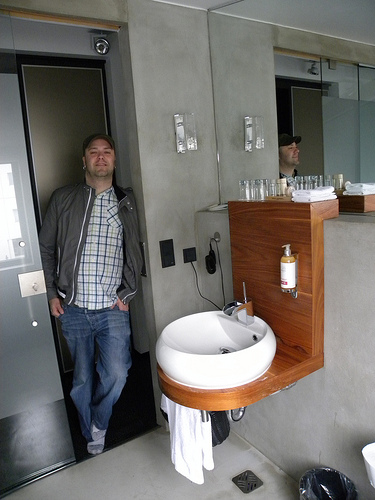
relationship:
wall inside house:
[133, 12, 211, 116] [236, 28, 294, 68]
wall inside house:
[0, 0, 375, 499] [236, 28, 294, 68]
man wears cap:
[42, 122, 138, 426] [81, 129, 121, 147]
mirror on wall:
[208, 4, 372, 217] [133, 12, 211, 116]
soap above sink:
[279, 243, 297, 293] [156, 308, 286, 389]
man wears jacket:
[42, 122, 138, 426] [53, 182, 144, 308]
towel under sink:
[158, 394, 215, 486] [156, 308, 286, 389]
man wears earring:
[42, 122, 138, 426] [78, 165, 93, 177]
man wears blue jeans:
[42, 122, 138, 426] [56, 303, 132, 439]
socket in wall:
[176, 247, 200, 264] [133, 12, 211, 116]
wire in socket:
[178, 267, 215, 305] [176, 247, 200, 264]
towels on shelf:
[293, 189, 343, 203] [228, 201, 348, 246]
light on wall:
[169, 108, 203, 159] [133, 12, 211, 116]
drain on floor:
[228, 468, 264, 493] [60, 468, 179, 497]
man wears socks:
[42, 122, 138, 426] [83, 425, 107, 456]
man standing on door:
[42, 135, 143, 449] [0, 51, 156, 498]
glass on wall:
[146, 106, 213, 154] [129, 16, 225, 333]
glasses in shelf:
[240, 181, 251, 201] [229, 194, 338, 205]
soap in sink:
[279, 243, 297, 293] [144, 275, 283, 397]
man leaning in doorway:
[42, 135, 143, 449] [0, 16, 163, 497]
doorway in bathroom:
[0, 16, 163, 497] [2, 0, 373, 497]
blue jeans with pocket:
[56, 303, 132, 439] [112, 305, 129, 323]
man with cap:
[42, 135, 143, 449] [82, 132, 114, 154]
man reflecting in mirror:
[42, 135, 143, 449] [208, 4, 372, 217]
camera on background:
[89, 32, 116, 57] [60, 20, 177, 152]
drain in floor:
[228, 468, 264, 493] [7, 424, 298, 498]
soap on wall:
[264, 243, 331, 304] [275, 297, 352, 340]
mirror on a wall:
[208, 4, 372, 217] [168, 25, 333, 320]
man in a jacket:
[42, 135, 143, 449] [41, 185, 143, 302]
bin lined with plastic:
[292, 459, 359, 499] [293, 455, 362, 497]